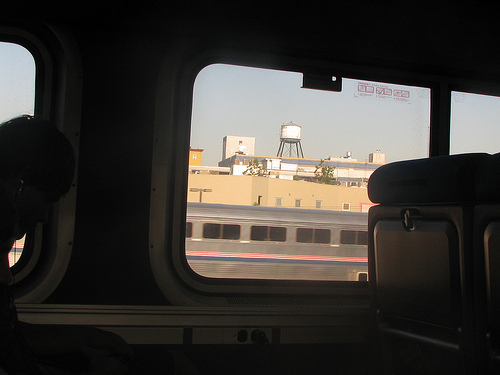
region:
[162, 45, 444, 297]
Window in a train.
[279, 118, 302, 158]
A white water tower.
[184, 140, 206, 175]
An orange building.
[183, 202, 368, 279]
A silver train car with a red and blue stripe.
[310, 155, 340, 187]
A large bush or tree in between buildings.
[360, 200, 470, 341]
A seat back tray in the upright position.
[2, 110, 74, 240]
A person's head.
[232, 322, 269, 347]
Two electrical outlets.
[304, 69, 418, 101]
Window latch and instructions.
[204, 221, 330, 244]
Windows on the train.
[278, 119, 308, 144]
this is a tank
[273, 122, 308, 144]
the tank is round in shape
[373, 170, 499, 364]
these are seats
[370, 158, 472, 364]
the seats are black in color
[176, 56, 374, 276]
this is the window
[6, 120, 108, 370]
this is a person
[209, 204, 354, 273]
this is a train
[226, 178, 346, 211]
this is a building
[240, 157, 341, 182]
these are trees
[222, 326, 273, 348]
these are sockets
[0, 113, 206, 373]
person is looking down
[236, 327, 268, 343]
power outlet in front of person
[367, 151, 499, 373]
train seats in front of person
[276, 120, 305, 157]
water tower above buildings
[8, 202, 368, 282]
train is moving in background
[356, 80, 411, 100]
red instructions on window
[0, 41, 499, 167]
sky is blue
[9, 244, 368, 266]
train has blue and red stripes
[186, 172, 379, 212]
tan building behind train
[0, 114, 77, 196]
person has hair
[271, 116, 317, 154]
a water tower standing in the distance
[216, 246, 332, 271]
blue and red lines on a train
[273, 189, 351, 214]
windows in a building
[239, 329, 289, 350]
safety latch on the window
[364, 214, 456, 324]
pull out tray on seat back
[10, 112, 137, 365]
a man looking at his cell phone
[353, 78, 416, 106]
safety stickers on the window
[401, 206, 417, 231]
latch on seat trau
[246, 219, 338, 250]
windows on another train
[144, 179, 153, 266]
metal screws in window frame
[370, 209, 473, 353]
Folding tray on back of train seat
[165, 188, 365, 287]
Train seen from inside another train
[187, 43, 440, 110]
Train window latch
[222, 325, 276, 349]
Train power outlet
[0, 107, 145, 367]
Train passenger sitting down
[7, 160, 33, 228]
Train passenger wearing headphones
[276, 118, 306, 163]
White water tower seen from train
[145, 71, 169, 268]
Screws holding train window fram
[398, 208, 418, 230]
Latch on seat fold-down tray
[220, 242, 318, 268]
Silver train with red and blue stripes